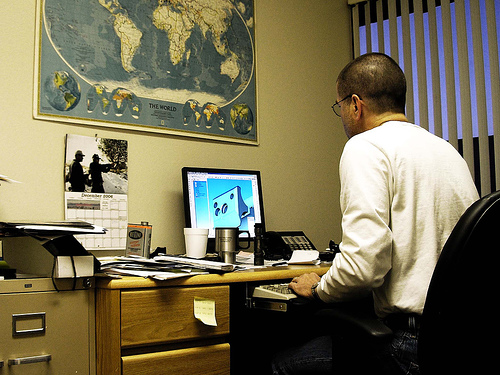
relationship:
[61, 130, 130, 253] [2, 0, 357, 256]
calendar on wall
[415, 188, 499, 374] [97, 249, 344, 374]
chair next to desk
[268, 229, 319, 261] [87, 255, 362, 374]
phone on desk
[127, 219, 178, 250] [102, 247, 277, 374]
can on desk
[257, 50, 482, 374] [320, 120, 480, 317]
man wearing shirt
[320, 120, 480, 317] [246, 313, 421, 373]
shirt and jeans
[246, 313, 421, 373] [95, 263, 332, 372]
jeans sitting at desk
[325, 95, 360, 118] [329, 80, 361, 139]
glasses on face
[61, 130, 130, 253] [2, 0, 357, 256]
calendar hanging on wall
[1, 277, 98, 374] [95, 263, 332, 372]
cabinet next to desk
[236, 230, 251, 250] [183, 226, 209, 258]
handle on cup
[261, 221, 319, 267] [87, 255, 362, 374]
phone on desk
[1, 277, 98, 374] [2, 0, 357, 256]
cabinet against wall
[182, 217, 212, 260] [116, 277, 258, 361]
cup sitting on desk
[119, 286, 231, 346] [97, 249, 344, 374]
drawer on desk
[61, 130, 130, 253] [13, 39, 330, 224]
calendar on wall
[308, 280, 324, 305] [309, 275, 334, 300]
watch on wrist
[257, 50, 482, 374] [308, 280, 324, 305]
man wearing watch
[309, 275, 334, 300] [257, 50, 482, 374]
wrist on man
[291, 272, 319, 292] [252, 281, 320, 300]
hand on keyboard